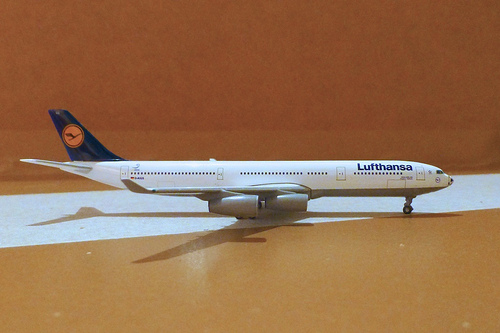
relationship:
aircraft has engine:
[19, 106, 454, 220] [260, 190, 310, 213]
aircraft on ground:
[19, 106, 454, 220] [1, 169, 498, 326]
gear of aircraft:
[395, 202, 424, 221] [9, 87, 471, 264]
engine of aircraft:
[199, 196, 265, 218] [17, 103, 457, 229]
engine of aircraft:
[252, 192, 349, 201] [17, 103, 457, 229]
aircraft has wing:
[19, 106, 454, 220] [121, 177, 151, 194]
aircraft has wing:
[19, 106, 454, 220] [114, 163, 308, 203]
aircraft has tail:
[19, 106, 454, 220] [39, 103, 119, 159]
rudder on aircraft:
[40, 100, 120, 160] [17, 103, 457, 229]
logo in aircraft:
[59, 119, 91, 161] [17, 103, 457, 229]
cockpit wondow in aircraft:
[435, 169, 445, 174] [19, 106, 454, 220]